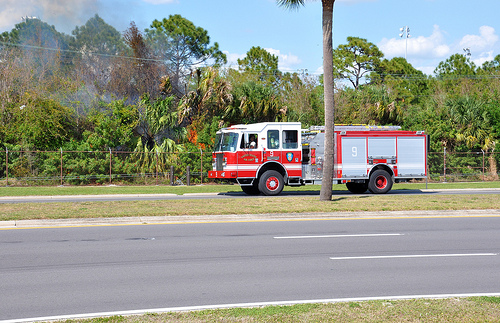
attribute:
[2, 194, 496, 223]
grassy area — green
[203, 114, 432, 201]
truck — fire truck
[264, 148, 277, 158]
9 — number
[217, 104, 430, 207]
truck — white, red, fire truck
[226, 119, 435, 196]
truck — fire truck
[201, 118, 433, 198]
fire truck — red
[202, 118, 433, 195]
truck — moving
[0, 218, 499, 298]
roadway — paved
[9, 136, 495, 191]
fence — chain link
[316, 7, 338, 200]
tree — palm tree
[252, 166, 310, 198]
rims — red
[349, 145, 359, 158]
9 — number